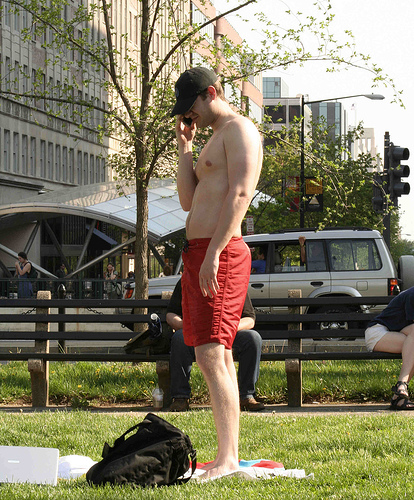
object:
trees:
[0, 0, 407, 342]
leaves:
[123, 111, 128, 120]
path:
[0, 409, 414, 420]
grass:
[290, 412, 383, 484]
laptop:
[0, 445, 60, 486]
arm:
[300, 244, 305, 266]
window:
[273, 241, 307, 273]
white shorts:
[364, 324, 389, 354]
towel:
[178, 458, 315, 484]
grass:
[227, 479, 359, 497]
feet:
[191, 465, 242, 485]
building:
[262, 94, 313, 164]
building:
[307, 101, 348, 160]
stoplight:
[383, 132, 410, 209]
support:
[285, 288, 302, 408]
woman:
[104, 263, 119, 300]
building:
[0, 0, 263, 305]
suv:
[115, 228, 414, 341]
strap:
[172, 439, 197, 488]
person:
[364, 287, 412, 410]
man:
[170, 65, 264, 482]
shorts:
[181, 234, 251, 350]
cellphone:
[182, 116, 194, 128]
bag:
[85, 412, 197, 490]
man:
[165, 275, 264, 412]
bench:
[0, 296, 402, 411]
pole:
[383, 132, 391, 254]